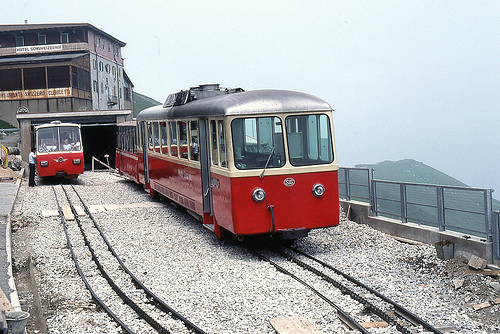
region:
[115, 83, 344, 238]
train on the track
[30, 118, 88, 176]
train on the track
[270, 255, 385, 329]
track train is on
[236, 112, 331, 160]
window on the train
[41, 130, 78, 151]
window on the train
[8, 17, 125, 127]
building behind the trains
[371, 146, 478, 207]
elevated terrain in the distance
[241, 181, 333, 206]
lights on the train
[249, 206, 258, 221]
part of a train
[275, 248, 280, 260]
part of a rock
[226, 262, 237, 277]
edge of a rock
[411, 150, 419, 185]
part of a rail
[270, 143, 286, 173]
part of a window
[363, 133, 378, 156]
edge of a hill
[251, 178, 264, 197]
part of a light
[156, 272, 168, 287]
part of a rock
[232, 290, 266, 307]
gray rock on track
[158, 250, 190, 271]
gray rock on track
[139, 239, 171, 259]
gray rock on track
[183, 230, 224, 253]
gray rock on track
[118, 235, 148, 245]
gray rock on track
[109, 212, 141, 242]
gray rock on track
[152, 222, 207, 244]
gray rock on track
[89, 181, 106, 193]
gray rock on track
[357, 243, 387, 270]
gray rock on track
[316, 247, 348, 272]
gray rock on track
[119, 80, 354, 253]
A stopped passenger train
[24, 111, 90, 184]
A man standing next to a passenger train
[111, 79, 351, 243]
A silver and red passenger train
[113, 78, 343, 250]
An old silver and red passenger train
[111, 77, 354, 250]
A parked silver and red passenger train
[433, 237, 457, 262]
A rusty tin trash can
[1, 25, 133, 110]
An old delapitated building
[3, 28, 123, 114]
An old delapitated building with rust stains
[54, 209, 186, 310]
Narrow train tracks with white gravel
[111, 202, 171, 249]
A bunch of white gravel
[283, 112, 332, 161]
window on a train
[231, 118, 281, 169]
window on a train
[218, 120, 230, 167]
window on a train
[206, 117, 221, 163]
window on a train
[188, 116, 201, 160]
window on a train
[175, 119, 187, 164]
window on a train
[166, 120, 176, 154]
window on a train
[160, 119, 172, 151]
window on a train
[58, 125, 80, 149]
window on a train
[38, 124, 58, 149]
window on a train